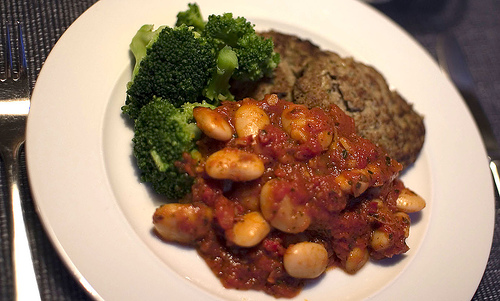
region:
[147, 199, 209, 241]
a bean in a tomato sauce dish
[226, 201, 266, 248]
a bean in a tomato sauce dish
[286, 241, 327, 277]
a bean in a tomato sauce dish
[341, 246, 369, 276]
a bean in a tomato sauce dish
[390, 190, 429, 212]
a bean in a tomato sauce dish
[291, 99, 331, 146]
a bean in a tomato sauce dish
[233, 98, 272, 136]
a bean in a tomato sauce dish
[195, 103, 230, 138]
a bean in a tomato sauce dish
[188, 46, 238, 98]
a broccoli floret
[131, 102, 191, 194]
a broccoli floret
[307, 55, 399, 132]
a slab of brown meat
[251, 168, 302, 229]
a piece of some garlic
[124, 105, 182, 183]
the bush of some broccoli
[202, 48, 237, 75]
the stem of some broccoli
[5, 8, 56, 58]
the place mat on a table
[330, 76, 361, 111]
a wrinkle on some meat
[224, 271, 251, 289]
a speck of spices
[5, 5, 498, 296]
white plate on dark woven mat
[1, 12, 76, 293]
shiny silver fork next to plate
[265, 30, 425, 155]
overlapping brown meat patties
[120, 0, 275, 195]
pieces of broccoli including stalks and florets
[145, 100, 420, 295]
white beans covered in tomato sauce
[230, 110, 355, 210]
dark flecks of seasoning in sauce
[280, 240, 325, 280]
smooth and plump bean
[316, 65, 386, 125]
flap of browned crust on meat surface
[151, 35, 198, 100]
tightly closed florets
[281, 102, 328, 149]
bean covered in sauce and seasoning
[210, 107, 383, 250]
beans on the plate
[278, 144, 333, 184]
sauce on the beans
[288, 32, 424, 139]
meat on the plate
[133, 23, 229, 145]
broccoli on the plate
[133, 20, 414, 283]
a pile of food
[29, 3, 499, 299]
food on a plate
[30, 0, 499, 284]
a white plate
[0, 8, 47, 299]
a fork next to the plate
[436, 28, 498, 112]
a knife next to the plate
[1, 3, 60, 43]
a place mat under the plate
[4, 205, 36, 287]
There is a fork that is visible here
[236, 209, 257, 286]
There is a bean casserole here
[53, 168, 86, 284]
There is a white plate here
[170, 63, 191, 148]
There is broccoli here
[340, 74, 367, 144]
There are some hamburgers here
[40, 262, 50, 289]
There is a placemat here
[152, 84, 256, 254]
Jackson Mingus took this photo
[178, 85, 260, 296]
This photo was taken with a telephoto lens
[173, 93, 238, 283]
This photo has a very high quality